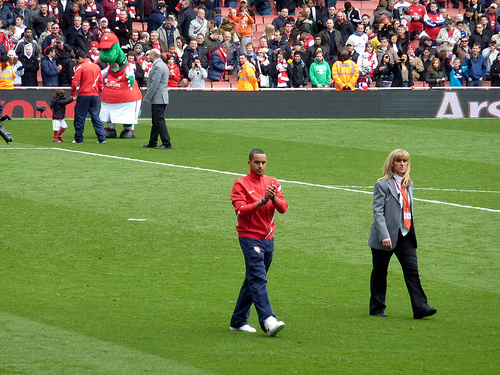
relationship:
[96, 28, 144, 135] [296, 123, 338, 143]
mascot on field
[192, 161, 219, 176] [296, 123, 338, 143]
markers on field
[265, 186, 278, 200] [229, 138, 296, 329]
hands of man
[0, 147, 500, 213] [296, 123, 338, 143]
markers on field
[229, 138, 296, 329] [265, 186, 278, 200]
man holding hands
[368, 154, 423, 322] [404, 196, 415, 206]
woman wearing tie